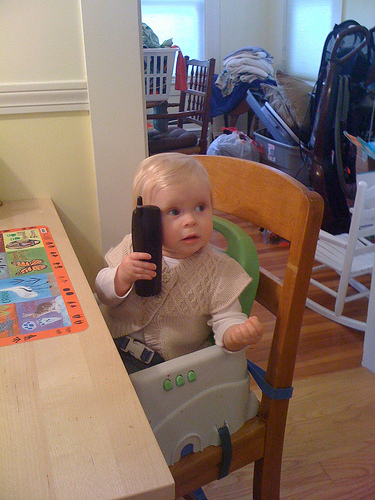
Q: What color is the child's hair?
A: Blonde.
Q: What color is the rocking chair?
A: White.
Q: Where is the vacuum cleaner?
A: On the floor.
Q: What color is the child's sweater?
A: Tan.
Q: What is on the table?
A: A placemat.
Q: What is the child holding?
A: A phone.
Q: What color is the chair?
A: Brown.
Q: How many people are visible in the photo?
A: One.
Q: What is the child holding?
A: A phone.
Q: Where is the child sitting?
A: In a booster seat.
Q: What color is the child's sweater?
A: Beige.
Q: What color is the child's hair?
A: Blonde.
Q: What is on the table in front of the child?
A: A placemat.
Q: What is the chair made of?
A: Wood.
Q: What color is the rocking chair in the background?
A: White.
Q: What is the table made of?
A: Wood.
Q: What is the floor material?
A: Wood.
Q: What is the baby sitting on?
A: A booster seat.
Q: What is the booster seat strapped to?
A: A wooden chair.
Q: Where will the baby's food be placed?
A: On the placemat.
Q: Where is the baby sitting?
A: At a table.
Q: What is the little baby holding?
A: She's holding a black phone.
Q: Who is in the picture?
A: A baby girl is in the picture.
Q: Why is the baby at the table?
A: The baby is probably getting ready to eat.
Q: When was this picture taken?
A: In the daytime.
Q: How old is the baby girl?
A: She looks about 1-2 years old.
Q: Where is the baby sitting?
A: She is sitting at the dinner table.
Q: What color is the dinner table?
A: The table is light brown.